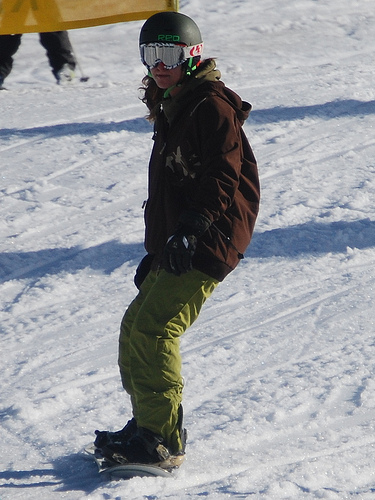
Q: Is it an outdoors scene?
A: Yes, it is outdoors.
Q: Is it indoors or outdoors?
A: It is outdoors.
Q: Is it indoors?
A: No, it is outdoors.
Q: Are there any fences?
A: No, there are no fences.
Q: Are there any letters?
A: Yes, there are letters.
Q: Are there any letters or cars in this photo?
A: Yes, there are letters.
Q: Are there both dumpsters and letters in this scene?
A: No, there are letters but no dumpsters.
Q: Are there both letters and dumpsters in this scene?
A: No, there are letters but no dumpsters.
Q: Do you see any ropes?
A: No, there are no ropes.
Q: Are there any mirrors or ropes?
A: No, there are no ropes or mirrors.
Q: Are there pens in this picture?
A: No, there are no pens.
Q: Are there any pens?
A: No, there are no pens.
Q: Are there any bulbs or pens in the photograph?
A: No, there are no pens or bulbs.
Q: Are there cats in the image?
A: No, there are no cats.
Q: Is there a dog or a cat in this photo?
A: No, there are no cats or dogs.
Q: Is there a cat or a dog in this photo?
A: No, there are no cats or dogs.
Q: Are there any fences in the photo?
A: No, there are no fences.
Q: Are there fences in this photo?
A: No, there are no fences.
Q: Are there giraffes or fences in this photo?
A: No, there are no fences or giraffes.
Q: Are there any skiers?
A: No, there are no skiers.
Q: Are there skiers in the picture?
A: No, there are no skiers.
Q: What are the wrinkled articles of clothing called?
A: The clothing items are snow pants.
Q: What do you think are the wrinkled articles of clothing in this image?
A: The clothing items are snow pants.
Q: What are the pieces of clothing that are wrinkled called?
A: The clothing items are snow pants.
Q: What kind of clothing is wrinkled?
A: The clothing is snow pants.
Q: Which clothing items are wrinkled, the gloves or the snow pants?
A: The snow pants are wrinkled.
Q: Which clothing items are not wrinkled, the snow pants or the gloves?
A: The gloves are not wrinkled.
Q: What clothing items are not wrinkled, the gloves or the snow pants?
A: The gloves are not wrinkled.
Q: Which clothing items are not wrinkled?
A: The clothing items are gloves.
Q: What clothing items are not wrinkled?
A: The clothing items are gloves.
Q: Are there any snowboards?
A: Yes, there is a snowboard.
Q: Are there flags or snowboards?
A: Yes, there is a snowboard.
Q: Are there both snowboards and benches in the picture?
A: No, there is a snowboard but no benches.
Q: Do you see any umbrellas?
A: No, there are no umbrellas.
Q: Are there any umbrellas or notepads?
A: No, there are no umbrellas or notepads.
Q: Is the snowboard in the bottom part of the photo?
A: Yes, the snowboard is in the bottom of the image.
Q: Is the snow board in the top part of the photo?
A: No, the snow board is in the bottom of the image.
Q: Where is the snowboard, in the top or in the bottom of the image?
A: The snowboard is in the bottom of the image.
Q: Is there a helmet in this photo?
A: Yes, there is a helmet.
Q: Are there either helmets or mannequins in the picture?
A: Yes, there is a helmet.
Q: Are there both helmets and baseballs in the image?
A: No, there is a helmet but no baseballs.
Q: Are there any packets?
A: No, there are no packets.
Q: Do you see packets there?
A: No, there are no packets.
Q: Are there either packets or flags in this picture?
A: No, there are no packets or flags.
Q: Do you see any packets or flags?
A: No, there are no packets or flags.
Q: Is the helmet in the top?
A: Yes, the helmet is in the top of the image.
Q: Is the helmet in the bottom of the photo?
A: No, the helmet is in the top of the image.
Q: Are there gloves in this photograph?
A: Yes, there are gloves.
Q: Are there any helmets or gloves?
A: Yes, there are gloves.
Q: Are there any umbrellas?
A: No, there are no umbrellas.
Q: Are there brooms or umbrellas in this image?
A: No, there are no umbrellas or brooms.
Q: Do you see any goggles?
A: Yes, there are goggles.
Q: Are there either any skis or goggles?
A: Yes, there are goggles.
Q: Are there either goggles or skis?
A: Yes, there are goggles.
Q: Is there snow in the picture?
A: Yes, there is snow.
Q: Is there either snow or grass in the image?
A: Yes, there is snow.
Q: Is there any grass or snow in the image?
A: Yes, there is snow.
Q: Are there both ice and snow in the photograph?
A: No, there is snow but no ice.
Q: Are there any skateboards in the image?
A: No, there are no skateboards.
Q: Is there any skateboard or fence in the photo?
A: No, there are no skateboards or fences.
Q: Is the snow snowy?
A: Yes, the snow is snowy.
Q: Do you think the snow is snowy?
A: Yes, the snow is snowy.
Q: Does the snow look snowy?
A: Yes, the snow is snowy.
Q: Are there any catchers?
A: No, there are no catchers.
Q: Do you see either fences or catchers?
A: No, there are no catchers or fences.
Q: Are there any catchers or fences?
A: No, there are no catchers or fences.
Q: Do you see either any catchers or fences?
A: No, there are no catchers or fences.